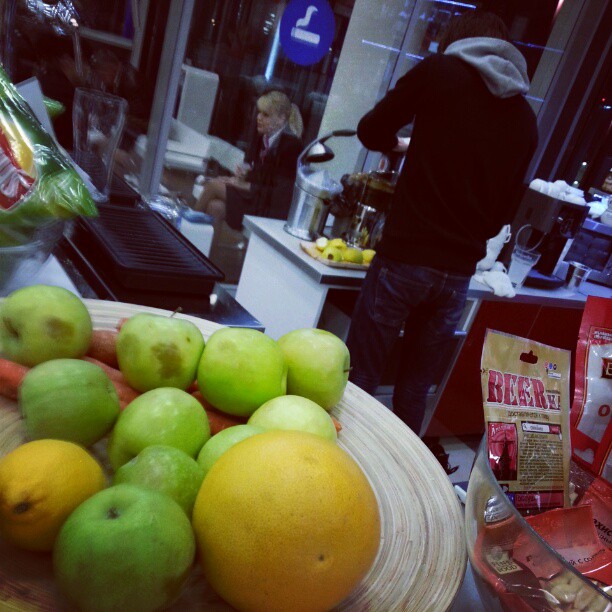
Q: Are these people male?
A: No, they are both male and female.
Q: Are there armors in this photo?
A: No, there are no armors.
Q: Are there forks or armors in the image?
A: No, there are no armors or forks.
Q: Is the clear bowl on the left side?
A: Yes, the bowl is on the left of the image.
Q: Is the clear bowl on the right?
A: No, the bowl is on the left of the image.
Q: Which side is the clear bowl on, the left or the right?
A: The bowl is on the left of the image.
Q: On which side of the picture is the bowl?
A: The bowl is on the left of the image.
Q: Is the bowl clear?
A: Yes, the bowl is clear.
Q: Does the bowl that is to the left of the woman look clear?
A: Yes, the bowl is clear.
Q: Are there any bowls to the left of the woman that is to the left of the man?
A: Yes, there is a bowl to the left of the woman.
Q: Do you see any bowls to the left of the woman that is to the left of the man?
A: Yes, there is a bowl to the left of the woman.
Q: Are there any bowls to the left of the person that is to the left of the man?
A: Yes, there is a bowl to the left of the woman.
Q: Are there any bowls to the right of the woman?
A: No, the bowl is to the left of the woman.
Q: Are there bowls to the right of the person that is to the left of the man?
A: No, the bowl is to the left of the woman.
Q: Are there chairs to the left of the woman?
A: No, there is a bowl to the left of the woman.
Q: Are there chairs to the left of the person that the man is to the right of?
A: No, there is a bowl to the left of the woman.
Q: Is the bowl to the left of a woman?
A: Yes, the bowl is to the left of a woman.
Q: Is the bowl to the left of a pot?
A: No, the bowl is to the left of a woman.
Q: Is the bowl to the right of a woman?
A: No, the bowl is to the left of a woman.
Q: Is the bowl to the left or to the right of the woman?
A: The bowl is to the left of the woman.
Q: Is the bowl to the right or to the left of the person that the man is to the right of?
A: The bowl is to the left of the woman.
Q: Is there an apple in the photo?
A: Yes, there is an apple.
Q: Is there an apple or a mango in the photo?
A: Yes, there is an apple.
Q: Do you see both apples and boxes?
A: No, there is an apple but no boxes.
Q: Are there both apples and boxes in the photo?
A: No, there is an apple but no boxes.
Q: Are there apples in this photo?
A: Yes, there is an apple.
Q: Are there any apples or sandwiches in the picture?
A: Yes, there is an apple.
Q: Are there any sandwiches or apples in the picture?
A: Yes, there is an apple.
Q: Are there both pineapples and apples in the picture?
A: No, there is an apple but no pineapples.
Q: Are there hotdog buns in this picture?
A: No, there are no hotdog buns.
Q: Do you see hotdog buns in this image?
A: No, there are no hotdog buns.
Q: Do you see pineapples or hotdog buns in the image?
A: No, there are no hotdog buns or pineapples.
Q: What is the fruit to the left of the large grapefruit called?
A: The fruit is an apple.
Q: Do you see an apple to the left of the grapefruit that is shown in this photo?
A: Yes, there is an apple to the left of the grapefruit.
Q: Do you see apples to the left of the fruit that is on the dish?
A: Yes, there is an apple to the left of the grapefruit.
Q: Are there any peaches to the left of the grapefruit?
A: No, there is an apple to the left of the grapefruit.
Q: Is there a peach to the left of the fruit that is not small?
A: No, there is an apple to the left of the grapefruit.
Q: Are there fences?
A: No, there are no fences.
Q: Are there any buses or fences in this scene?
A: No, there are no fences or buses.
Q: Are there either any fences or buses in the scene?
A: No, there are no fences or buses.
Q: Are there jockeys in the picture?
A: No, there are no jockeys.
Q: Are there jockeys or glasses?
A: No, there are no jockeys or glasses.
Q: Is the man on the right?
A: Yes, the man is on the right of the image.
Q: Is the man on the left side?
A: No, the man is on the right of the image.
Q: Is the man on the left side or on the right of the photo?
A: The man is on the right of the image.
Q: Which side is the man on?
A: The man is on the right of the image.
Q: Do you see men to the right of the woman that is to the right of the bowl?
A: Yes, there is a man to the right of the woman.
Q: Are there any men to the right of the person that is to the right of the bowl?
A: Yes, there is a man to the right of the woman.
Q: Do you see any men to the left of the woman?
A: No, the man is to the right of the woman.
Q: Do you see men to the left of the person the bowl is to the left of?
A: No, the man is to the right of the woman.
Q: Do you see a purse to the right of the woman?
A: No, there is a man to the right of the woman.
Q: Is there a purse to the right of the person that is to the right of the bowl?
A: No, there is a man to the right of the woman.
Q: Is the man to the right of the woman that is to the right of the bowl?
A: Yes, the man is to the right of the woman.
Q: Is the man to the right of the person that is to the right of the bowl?
A: Yes, the man is to the right of the woman.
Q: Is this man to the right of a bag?
A: No, the man is to the right of the woman.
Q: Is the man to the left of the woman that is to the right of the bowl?
A: No, the man is to the right of the woman.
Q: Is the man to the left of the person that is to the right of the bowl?
A: No, the man is to the right of the woman.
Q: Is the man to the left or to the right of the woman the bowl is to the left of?
A: The man is to the right of the woman.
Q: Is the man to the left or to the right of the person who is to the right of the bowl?
A: The man is to the right of the woman.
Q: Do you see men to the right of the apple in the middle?
A: Yes, there is a man to the right of the apple.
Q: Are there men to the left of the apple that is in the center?
A: No, the man is to the right of the apple.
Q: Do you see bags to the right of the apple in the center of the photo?
A: No, there is a man to the right of the apple.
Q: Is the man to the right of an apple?
A: Yes, the man is to the right of an apple.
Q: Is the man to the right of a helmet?
A: No, the man is to the right of an apple.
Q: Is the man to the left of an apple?
A: No, the man is to the right of an apple.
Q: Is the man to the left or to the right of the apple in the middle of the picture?
A: The man is to the right of the apple.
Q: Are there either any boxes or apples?
A: Yes, there is an apple.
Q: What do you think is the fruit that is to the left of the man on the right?
A: The fruit is an apple.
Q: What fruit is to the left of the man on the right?
A: The fruit is an apple.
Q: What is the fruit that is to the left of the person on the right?
A: The fruit is an apple.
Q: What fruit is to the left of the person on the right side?
A: The fruit is an apple.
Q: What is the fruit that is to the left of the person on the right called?
A: The fruit is an apple.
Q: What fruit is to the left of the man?
A: The fruit is an apple.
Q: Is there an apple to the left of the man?
A: Yes, there is an apple to the left of the man.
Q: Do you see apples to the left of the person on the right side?
A: Yes, there is an apple to the left of the man.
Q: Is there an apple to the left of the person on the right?
A: Yes, there is an apple to the left of the man.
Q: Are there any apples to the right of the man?
A: No, the apple is to the left of the man.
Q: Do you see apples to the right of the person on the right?
A: No, the apple is to the left of the man.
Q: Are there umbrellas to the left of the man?
A: No, there is an apple to the left of the man.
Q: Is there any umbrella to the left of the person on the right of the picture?
A: No, there is an apple to the left of the man.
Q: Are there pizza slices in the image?
A: No, there are no pizza slices.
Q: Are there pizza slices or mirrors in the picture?
A: No, there are no pizza slices or mirrors.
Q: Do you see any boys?
A: No, there are no boys.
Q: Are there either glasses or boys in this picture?
A: No, there are no boys or glasses.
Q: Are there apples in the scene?
A: Yes, there is an apple.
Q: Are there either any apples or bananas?
A: Yes, there is an apple.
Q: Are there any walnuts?
A: No, there are no walnuts.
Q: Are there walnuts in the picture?
A: No, there are no walnuts.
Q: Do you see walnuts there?
A: No, there are no walnuts.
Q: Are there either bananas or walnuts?
A: No, there are no walnuts or bananas.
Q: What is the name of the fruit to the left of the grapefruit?
A: The fruit is an apple.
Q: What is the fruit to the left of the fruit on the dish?
A: The fruit is an apple.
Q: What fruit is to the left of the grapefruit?
A: The fruit is an apple.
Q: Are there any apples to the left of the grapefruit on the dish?
A: Yes, there is an apple to the left of the grapefruit.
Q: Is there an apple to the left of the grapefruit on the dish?
A: Yes, there is an apple to the left of the grapefruit.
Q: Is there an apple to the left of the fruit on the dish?
A: Yes, there is an apple to the left of the grapefruit.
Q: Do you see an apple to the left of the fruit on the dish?
A: Yes, there is an apple to the left of the grapefruit.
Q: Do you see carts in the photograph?
A: No, there are no carts.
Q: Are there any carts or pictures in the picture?
A: No, there are no carts or pictures.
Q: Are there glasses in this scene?
A: No, there are no glasses.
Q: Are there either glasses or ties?
A: No, there are no glasses or ties.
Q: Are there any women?
A: Yes, there is a woman.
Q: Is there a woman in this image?
A: Yes, there is a woman.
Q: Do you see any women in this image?
A: Yes, there is a woman.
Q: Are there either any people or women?
A: Yes, there is a woman.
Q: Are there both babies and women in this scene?
A: No, there is a woman but no babies.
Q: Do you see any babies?
A: No, there are no babies.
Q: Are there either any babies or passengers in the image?
A: No, there are no babies or passengers.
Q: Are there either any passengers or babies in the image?
A: No, there are no babies or passengers.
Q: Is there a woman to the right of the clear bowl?
A: Yes, there is a woman to the right of the bowl.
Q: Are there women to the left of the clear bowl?
A: No, the woman is to the right of the bowl.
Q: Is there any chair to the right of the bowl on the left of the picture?
A: No, there is a woman to the right of the bowl.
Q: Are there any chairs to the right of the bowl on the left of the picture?
A: No, there is a woman to the right of the bowl.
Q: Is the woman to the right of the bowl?
A: Yes, the woman is to the right of the bowl.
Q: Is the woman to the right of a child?
A: No, the woman is to the right of the bowl.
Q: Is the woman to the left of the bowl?
A: No, the woman is to the right of the bowl.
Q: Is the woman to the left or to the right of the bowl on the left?
A: The woman is to the right of the bowl.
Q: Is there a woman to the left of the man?
A: Yes, there is a woman to the left of the man.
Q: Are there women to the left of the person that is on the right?
A: Yes, there is a woman to the left of the man.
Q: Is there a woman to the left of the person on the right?
A: Yes, there is a woman to the left of the man.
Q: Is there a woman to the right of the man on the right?
A: No, the woman is to the left of the man.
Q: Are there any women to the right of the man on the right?
A: No, the woman is to the left of the man.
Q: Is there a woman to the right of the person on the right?
A: No, the woman is to the left of the man.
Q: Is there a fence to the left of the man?
A: No, there is a woman to the left of the man.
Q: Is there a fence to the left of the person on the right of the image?
A: No, there is a woman to the left of the man.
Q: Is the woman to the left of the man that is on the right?
A: Yes, the woman is to the left of the man.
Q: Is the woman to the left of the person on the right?
A: Yes, the woman is to the left of the man.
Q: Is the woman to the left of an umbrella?
A: No, the woman is to the left of the man.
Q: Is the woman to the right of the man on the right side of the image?
A: No, the woman is to the left of the man.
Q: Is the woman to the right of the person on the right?
A: No, the woman is to the left of the man.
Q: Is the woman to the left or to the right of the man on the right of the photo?
A: The woman is to the left of the man.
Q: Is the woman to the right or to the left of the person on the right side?
A: The woman is to the left of the man.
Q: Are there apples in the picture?
A: Yes, there is an apple.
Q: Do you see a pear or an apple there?
A: Yes, there is an apple.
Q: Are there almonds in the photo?
A: No, there are no almonds.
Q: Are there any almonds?
A: No, there are no almonds.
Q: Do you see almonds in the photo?
A: No, there are no almonds.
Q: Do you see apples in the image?
A: Yes, there is an apple.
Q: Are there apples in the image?
A: Yes, there is an apple.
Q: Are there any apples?
A: Yes, there is an apple.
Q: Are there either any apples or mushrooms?
A: Yes, there is an apple.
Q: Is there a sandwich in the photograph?
A: No, there are no sandwiches.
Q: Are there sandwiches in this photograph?
A: No, there are no sandwiches.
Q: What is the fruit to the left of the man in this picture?
A: The fruit is an apple.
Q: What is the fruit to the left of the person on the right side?
A: The fruit is an apple.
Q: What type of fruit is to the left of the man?
A: The fruit is an apple.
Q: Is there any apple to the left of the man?
A: Yes, there is an apple to the left of the man.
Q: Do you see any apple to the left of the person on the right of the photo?
A: Yes, there is an apple to the left of the man.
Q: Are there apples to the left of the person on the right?
A: Yes, there is an apple to the left of the man.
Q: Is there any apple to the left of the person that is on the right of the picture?
A: Yes, there is an apple to the left of the man.